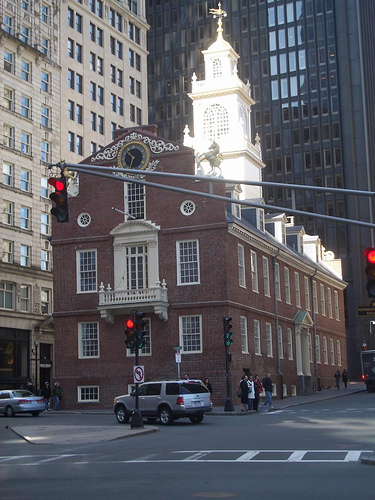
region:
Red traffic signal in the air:
[36, 162, 87, 226]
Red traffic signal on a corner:
[109, 309, 152, 429]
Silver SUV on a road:
[113, 371, 216, 429]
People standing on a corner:
[235, 369, 281, 420]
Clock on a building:
[114, 141, 162, 176]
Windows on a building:
[232, 305, 343, 375]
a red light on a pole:
[38, 155, 81, 228]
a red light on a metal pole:
[39, 158, 62, 242]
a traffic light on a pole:
[45, 158, 123, 234]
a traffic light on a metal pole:
[35, 156, 116, 225]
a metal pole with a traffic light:
[38, 157, 130, 220]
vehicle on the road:
[123, 374, 233, 421]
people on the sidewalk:
[239, 370, 292, 406]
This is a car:
[115, 371, 216, 427]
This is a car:
[0, 380, 64, 426]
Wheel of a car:
[156, 401, 179, 431]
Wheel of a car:
[108, 397, 128, 423]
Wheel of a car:
[4, 402, 13, 418]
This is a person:
[261, 370, 284, 418]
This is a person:
[251, 370, 265, 411]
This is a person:
[240, 368, 250, 411]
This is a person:
[249, 372, 257, 406]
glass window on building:
[77, 386, 101, 401]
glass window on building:
[77, 321, 98, 357]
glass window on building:
[128, 320, 150, 355]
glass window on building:
[179, 314, 200, 350]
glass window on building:
[77, 250, 96, 291]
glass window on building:
[175, 241, 199, 281]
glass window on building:
[0, 279, 15, 307]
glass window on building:
[20, 284, 29, 311]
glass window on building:
[42, 287, 51, 313]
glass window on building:
[19, 168, 30, 188]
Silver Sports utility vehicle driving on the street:
[113, 381, 216, 426]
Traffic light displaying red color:
[124, 311, 148, 351]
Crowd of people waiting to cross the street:
[240, 377, 275, 407]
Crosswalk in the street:
[35, 448, 352, 466]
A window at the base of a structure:
[78, 384, 101, 404]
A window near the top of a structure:
[77, 324, 100, 357]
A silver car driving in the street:
[0, 384, 45, 417]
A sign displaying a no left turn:
[132, 364, 147, 383]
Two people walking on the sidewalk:
[335, 365, 350, 392]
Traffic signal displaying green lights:
[221, 311, 236, 416]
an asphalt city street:
[0, 389, 374, 499]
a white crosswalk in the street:
[0, 449, 373, 466]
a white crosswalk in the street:
[260, 407, 374, 413]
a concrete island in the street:
[9, 424, 159, 443]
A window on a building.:
[171, 230, 205, 292]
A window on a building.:
[181, 313, 207, 354]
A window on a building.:
[122, 313, 153, 363]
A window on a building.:
[73, 383, 110, 401]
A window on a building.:
[73, 315, 109, 361]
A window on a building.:
[121, 243, 151, 290]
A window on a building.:
[124, 176, 149, 224]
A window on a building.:
[179, 200, 193, 213]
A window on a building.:
[174, 235, 219, 309]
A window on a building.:
[61, 245, 95, 299]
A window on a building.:
[232, 242, 251, 291]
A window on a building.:
[249, 245, 265, 294]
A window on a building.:
[259, 251, 272, 304]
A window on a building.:
[270, 260, 280, 310]